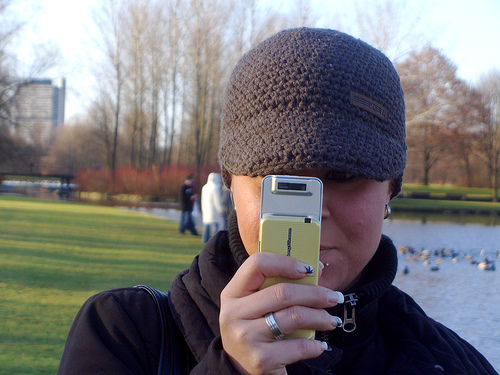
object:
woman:
[57, 27, 498, 374]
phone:
[258, 172, 326, 343]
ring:
[263, 311, 287, 341]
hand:
[216, 250, 346, 374]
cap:
[217, 26, 408, 197]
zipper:
[338, 289, 360, 333]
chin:
[312, 259, 351, 293]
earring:
[383, 202, 395, 221]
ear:
[383, 179, 393, 221]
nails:
[293, 258, 316, 278]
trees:
[85, 1, 135, 189]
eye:
[323, 167, 361, 184]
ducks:
[398, 264, 415, 277]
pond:
[383, 209, 499, 374]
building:
[0, 75, 68, 159]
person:
[201, 168, 232, 245]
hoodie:
[201, 169, 229, 226]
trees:
[397, 48, 499, 194]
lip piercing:
[323, 259, 333, 269]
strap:
[132, 278, 191, 374]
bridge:
[3, 169, 77, 190]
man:
[177, 175, 200, 238]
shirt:
[180, 186, 197, 212]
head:
[217, 26, 408, 297]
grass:
[3, 195, 208, 374]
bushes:
[79, 167, 201, 197]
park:
[1, 152, 499, 374]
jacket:
[57, 225, 496, 374]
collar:
[169, 229, 399, 353]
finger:
[257, 304, 344, 338]